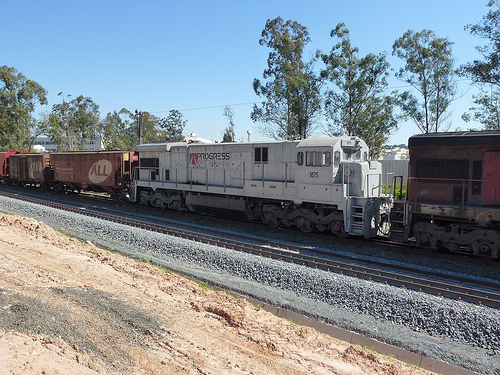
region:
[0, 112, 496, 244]
The trains are traveling down the track.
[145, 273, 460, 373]
The gravel next the train is called track ballast.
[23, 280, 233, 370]
Dirt on the ground.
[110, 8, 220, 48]
The sky is blue.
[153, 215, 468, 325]
An empty set of train tracks.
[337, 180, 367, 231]
A ladder on the train.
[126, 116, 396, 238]
A grey train car.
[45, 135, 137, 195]
A red and white train car.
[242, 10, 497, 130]
Trees behind the train.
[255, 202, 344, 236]
Wheels on the train.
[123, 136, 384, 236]
a white train engine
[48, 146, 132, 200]
a brown train coal car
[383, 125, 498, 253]
a red train engine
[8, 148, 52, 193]
a brown coal car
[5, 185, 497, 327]
a set of train tracks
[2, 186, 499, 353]
a grey stone railroad bed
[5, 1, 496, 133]
a solid blue sky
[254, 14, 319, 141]
a tall green tree in distance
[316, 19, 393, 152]
a tall green tree in distance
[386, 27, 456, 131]
a tall green tree in distance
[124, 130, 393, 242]
light grey train car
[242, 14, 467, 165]
tall sparse green trees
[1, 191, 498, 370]
gray gravel filled ditch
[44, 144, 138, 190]
rusty brown train car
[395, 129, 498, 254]
rust red metal train car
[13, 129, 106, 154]
long white building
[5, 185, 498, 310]
rusty metal train tracks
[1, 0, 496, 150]
clear bright blue sky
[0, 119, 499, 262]
commercial steam engine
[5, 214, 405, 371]
chinky brown dirt and gravel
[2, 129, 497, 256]
train on train tracks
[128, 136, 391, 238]
a white train car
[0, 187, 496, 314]
empty section of train tracks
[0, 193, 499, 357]
gravel on side of tracks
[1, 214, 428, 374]
dirt covered hill beside tracks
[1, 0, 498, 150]
trees on other side of train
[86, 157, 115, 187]
white circle with orange lettering inside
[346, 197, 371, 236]
small ladder on white train car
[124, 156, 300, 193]
outside walkway on white train car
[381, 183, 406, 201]
patch of green grass behind train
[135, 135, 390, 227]
A white train engine.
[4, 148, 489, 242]
A long cargo train.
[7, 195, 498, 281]
A set of train tracks.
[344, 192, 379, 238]
Stairs on a engine.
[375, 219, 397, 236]
A metal chain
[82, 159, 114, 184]
The word ALL on a red car.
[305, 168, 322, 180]
A set of numbers on a Engine.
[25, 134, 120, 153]
A large white building.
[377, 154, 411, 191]
A white fence.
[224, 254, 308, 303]
Gravel next to train tracks.